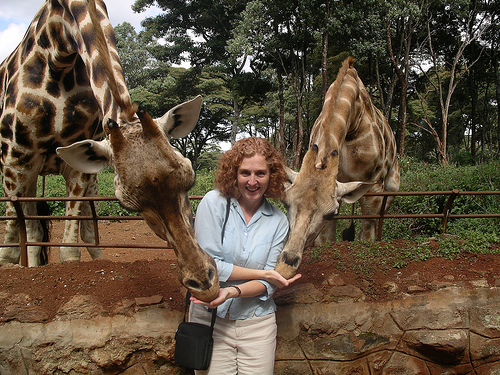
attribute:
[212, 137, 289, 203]
hair — brown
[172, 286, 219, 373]
bag — black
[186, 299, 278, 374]
pants — tan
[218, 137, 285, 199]
red hair — woman's, curly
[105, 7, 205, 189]
trees — tall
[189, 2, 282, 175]
trees — tall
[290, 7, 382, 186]
trees — tall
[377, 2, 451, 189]
trees — tall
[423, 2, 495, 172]
trees — tall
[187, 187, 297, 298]
shirt — blue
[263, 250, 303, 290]
hand — woman's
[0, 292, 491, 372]
wall — stone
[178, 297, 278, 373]
pants — tan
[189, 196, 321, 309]
shirt — light, blue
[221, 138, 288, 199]
curly hair — dark blonde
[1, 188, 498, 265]
fence — rust, colored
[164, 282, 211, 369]
purse — black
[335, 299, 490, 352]
rocks — brown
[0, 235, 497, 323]
soil — brown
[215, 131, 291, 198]
hair — red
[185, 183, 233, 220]
shoulder — woman's